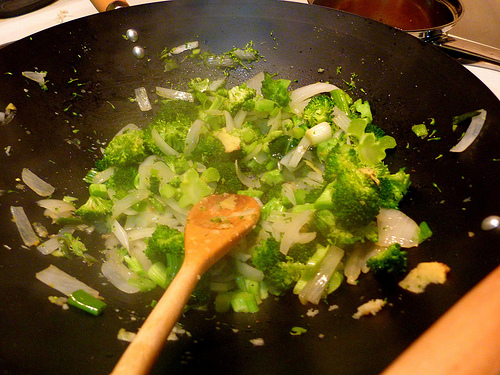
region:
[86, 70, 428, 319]
onions is part of the meal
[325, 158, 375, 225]
the broccoli is green in color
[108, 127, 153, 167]
the broccoli is green in color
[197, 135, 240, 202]
the broccoli is green in color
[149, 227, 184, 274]
the broccoli is green in color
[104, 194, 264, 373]
a spoon is in the meal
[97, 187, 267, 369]
the spoon is made of wood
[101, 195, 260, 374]
the wood is brown in color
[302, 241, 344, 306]
the onion is glistening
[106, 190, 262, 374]
Wooden spoon in the food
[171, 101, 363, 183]
Mixture of broccoli and onions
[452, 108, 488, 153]
Onion on the side of the wok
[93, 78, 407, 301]
Food being stirred in a wok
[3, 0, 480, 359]
A wok full of food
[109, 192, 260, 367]
Wooden spoon sitting in a wok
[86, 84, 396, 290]
Broccoli and onions in a wok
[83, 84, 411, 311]
Food cooking in a wok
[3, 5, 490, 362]
A black wok of food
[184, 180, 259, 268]
Head of a wooden spoon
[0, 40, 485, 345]
chopped onions and broccoli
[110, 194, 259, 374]
a spoon in the food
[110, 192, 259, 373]
the spoon is wood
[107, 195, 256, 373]
spoon is stirring the food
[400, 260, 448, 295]
piece of yellow vegetable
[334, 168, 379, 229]
a piece of broccoli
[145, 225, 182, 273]
the broccoli is green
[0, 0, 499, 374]
the skillet is black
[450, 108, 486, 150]
the onion is white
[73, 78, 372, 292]
a stir fry is being made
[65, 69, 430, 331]
making a stir fry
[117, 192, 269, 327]
the spoon is brown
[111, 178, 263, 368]
the spoon is wooden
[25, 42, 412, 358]
sauted vegetables being cooked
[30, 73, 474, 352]
these vegetables are being cooked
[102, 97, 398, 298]
the vegetables are green and white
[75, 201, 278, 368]
a wooden spoon for cooking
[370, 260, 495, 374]
a brown table next to the walk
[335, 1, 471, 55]
a metal pan in the background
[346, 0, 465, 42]
a sauce in a pan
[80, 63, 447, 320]
brocoli in the pan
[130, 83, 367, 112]
onions in the pan